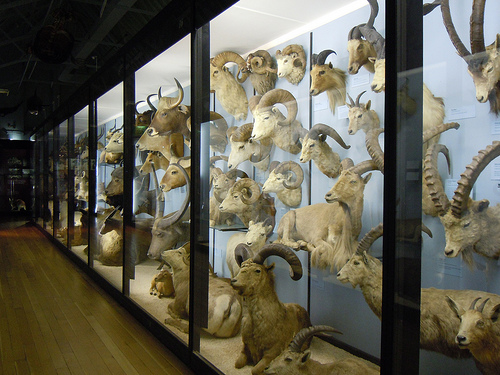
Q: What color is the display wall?
A: Blue.